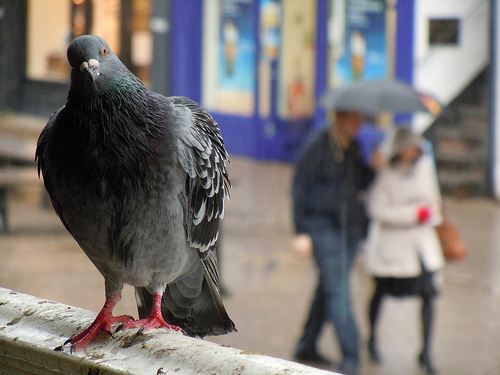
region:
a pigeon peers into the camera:
[22, 30, 315, 360]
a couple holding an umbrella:
[286, 79, 456, 371]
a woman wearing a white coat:
[368, 135, 455, 371]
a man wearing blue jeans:
[295, 110, 376, 365]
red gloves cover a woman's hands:
[417, 203, 436, 229]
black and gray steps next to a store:
[443, 83, 494, 192]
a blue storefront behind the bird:
[163, 0, 400, 67]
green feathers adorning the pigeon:
[94, 75, 147, 107]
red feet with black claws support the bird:
[61, 294, 179, 354]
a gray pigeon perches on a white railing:
[26, 30, 240, 365]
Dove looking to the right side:
[21, 31, 254, 362]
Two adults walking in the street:
[265, 65, 475, 370]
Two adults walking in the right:
[261, 58, 468, 373]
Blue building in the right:
[163, 5, 418, 176]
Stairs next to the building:
[425, 53, 496, 193]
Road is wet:
[0, 135, 496, 355]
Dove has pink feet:
[46, 276, 186, 356]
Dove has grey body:
[30, 30, 230, 300]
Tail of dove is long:
[127, 245, 237, 342]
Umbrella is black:
[307, 68, 451, 120]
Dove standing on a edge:
[27, 18, 251, 356]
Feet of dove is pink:
[52, 291, 187, 353]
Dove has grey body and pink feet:
[25, 31, 245, 358]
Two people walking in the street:
[272, 61, 476, 373]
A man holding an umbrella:
[281, 55, 463, 373]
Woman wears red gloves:
[357, 110, 479, 374]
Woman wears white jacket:
[362, 118, 457, 373]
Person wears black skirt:
[345, 117, 470, 374]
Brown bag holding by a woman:
[434, 198, 475, 265]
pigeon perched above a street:
[34, 36, 240, 356]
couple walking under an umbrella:
[291, 77, 445, 374]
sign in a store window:
[216, 3, 256, 92]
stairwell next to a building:
[415, 0, 486, 198]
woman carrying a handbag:
[360, 127, 445, 374]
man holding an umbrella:
[289, 94, 384, 372]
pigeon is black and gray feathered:
[34, 33, 238, 353]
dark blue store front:
[172, 1, 414, 164]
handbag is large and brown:
[435, 187, 469, 262]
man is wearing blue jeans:
[289, 108, 386, 373]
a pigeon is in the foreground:
[37, 34, 238, 347]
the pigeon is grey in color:
[27, 28, 237, 356]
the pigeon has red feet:
[57, 288, 193, 357]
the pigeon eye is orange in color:
[96, 44, 111, 58]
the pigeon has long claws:
[60, 312, 185, 354]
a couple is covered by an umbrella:
[292, 74, 448, 368]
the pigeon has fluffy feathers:
[34, 33, 231, 350]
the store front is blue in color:
[165, 6, 427, 183]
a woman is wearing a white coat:
[367, 156, 456, 282]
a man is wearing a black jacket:
[285, 124, 382, 239]